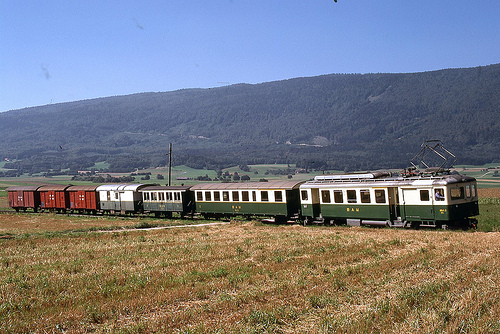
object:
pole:
[165, 142, 173, 186]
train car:
[5, 185, 40, 213]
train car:
[298, 170, 481, 232]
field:
[1, 211, 499, 334]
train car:
[94, 180, 160, 216]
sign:
[232, 205, 242, 214]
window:
[346, 189, 358, 204]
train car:
[189, 181, 310, 222]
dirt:
[1, 214, 62, 230]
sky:
[1, 0, 499, 112]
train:
[7, 171, 480, 232]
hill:
[0, 62, 500, 164]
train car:
[36, 184, 70, 214]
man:
[434, 187, 444, 201]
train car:
[66, 184, 99, 215]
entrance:
[386, 186, 402, 226]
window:
[450, 187, 465, 200]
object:
[409, 139, 457, 178]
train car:
[138, 185, 195, 219]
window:
[334, 190, 344, 203]